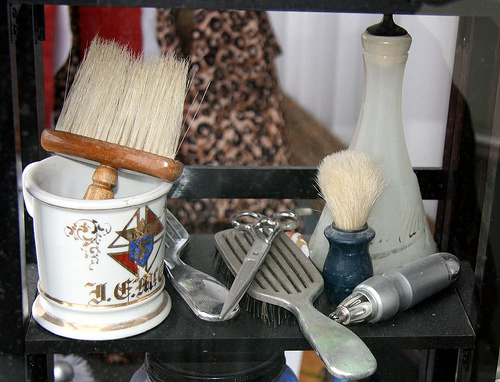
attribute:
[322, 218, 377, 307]
handle — blue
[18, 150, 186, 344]
mug — ceramic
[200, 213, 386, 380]
brush — Metal 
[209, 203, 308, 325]
scissors — Metal 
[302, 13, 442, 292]
lamp — White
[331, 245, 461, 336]
hair trimmer — silver nosed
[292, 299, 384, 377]
handle — silver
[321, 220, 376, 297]
handle — Blue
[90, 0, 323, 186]
mirror — Clear 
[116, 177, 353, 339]
scissors — silver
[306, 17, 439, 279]
bottle — white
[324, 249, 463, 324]
hair clipper — electric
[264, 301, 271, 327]
bristle — soft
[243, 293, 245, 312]
bristle — soft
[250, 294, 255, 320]
bristle — soft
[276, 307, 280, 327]
bristle — soft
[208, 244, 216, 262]
bristle — soft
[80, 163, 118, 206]
handle — wood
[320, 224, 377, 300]
handle — blue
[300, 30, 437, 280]
jar — white, glass